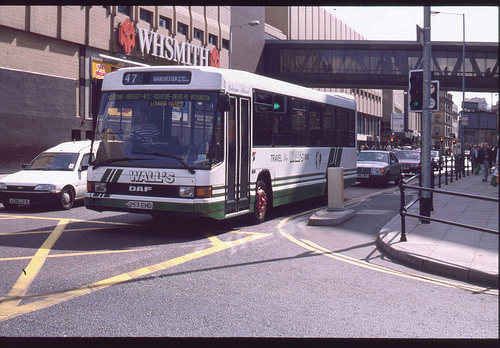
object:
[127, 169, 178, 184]
wall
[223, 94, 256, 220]
double doors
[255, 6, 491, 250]
right of bus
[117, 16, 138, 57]
red design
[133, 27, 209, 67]
business name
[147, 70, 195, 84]
marquee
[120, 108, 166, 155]
man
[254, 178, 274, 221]
bus wheel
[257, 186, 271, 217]
red hub cap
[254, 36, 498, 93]
bridge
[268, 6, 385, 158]
buildings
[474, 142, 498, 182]
people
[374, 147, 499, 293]
sidewalk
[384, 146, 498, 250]
iron gate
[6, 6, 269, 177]
building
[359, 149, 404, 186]
car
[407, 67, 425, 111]
street light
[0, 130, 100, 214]
car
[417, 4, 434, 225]
pole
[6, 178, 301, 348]
down  street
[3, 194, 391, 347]
intersection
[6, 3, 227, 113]
bookstore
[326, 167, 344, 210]
barrier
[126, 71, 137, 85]
47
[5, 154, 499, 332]
city street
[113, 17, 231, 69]
sign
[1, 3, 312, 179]
business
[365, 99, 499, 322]
corner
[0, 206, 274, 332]
yellow lines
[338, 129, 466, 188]
traffic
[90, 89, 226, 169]
front window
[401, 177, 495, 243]
barrier